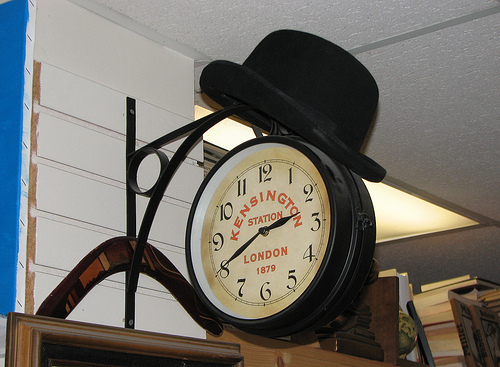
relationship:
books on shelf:
[397, 273, 499, 367] [362, 275, 499, 364]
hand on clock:
[266, 211, 300, 230] [184, 135, 376, 337]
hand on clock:
[217, 232, 261, 276] [184, 135, 376, 337]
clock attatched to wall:
[184, 135, 376, 337] [37, 1, 206, 339]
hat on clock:
[200, 29, 384, 184] [184, 135, 376, 337]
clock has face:
[184, 135, 376, 337] [201, 148, 332, 316]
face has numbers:
[201, 148, 332, 316] [210, 162, 319, 304]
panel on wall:
[30, 216, 198, 304] [37, 1, 206, 339]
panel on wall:
[35, 219, 187, 294] [37, 1, 206, 339]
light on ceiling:
[196, 107, 477, 243] [76, 0, 497, 289]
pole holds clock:
[126, 98, 287, 331] [184, 135, 376, 337]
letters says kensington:
[230, 190, 301, 275] [229, 189, 301, 242]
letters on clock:
[230, 190, 301, 275] [184, 135, 376, 337]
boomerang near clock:
[38, 238, 225, 335] [184, 135, 376, 337]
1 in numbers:
[287, 166, 294, 190] [210, 162, 319, 304]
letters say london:
[230, 190, 301, 275] [243, 245, 289, 265]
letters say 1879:
[230, 190, 301, 275] [257, 265, 276, 275]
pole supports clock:
[126, 98, 287, 331] [184, 135, 376, 337]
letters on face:
[230, 190, 301, 275] [201, 148, 332, 316]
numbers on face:
[210, 162, 319, 304] [201, 148, 332, 316]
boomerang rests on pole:
[38, 238, 225, 335] [126, 98, 287, 331]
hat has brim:
[200, 29, 384, 184] [200, 61, 386, 182]